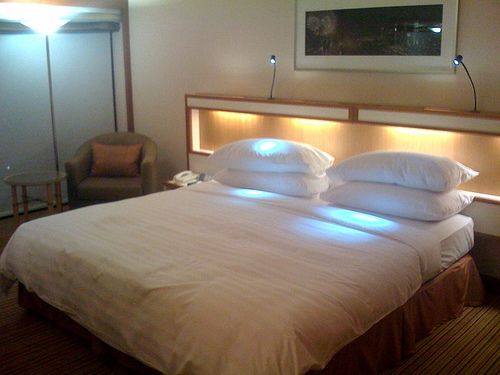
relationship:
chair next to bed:
[52, 116, 166, 190] [13, 175, 477, 373]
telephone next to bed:
[172, 169, 227, 199] [98, 179, 396, 330]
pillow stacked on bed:
[193, 134, 479, 223] [13, 175, 477, 373]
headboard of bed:
[184, 86, 496, 235] [13, 175, 477, 373]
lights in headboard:
[224, 90, 475, 174] [181, 92, 497, 186]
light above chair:
[19, 12, 77, 163] [63, 126, 163, 204]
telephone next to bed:
[171, 168, 201, 185] [5, 137, 479, 372]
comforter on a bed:
[28, 145, 457, 334] [15, 118, 468, 373]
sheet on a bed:
[286, 199, 329, 231] [43, 208, 495, 360]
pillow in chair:
[196, 117, 430, 222] [39, 117, 172, 196]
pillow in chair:
[196, 117, 430, 222] [52, 116, 166, 190]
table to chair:
[4, 169, 68, 228] [52, 116, 166, 190]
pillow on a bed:
[90, 142, 145, 179] [7, 139, 424, 356]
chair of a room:
[52, 116, 166, 190] [8, 28, 478, 371]